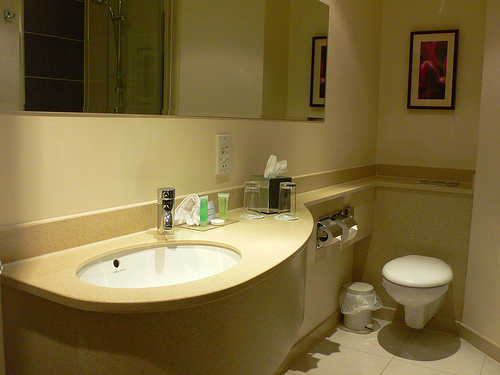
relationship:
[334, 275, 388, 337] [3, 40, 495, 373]
trash can in a bathroom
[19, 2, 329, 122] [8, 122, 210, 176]
mirror on wall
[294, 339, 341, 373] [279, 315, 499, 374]
shadows on floor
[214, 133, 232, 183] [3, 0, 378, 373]
outlet on wall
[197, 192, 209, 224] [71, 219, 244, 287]
shampoo on sink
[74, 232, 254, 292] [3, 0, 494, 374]
sink in bathroom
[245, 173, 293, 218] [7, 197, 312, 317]
box on counter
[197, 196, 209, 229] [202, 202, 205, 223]
bottle of soap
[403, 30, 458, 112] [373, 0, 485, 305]
picture on wall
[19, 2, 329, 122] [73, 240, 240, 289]
mirror above sink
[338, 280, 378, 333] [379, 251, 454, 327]
trash can next to toilet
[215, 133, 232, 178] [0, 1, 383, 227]
outlet on wall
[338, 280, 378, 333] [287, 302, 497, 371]
trash can on floor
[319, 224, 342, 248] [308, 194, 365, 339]
paper roll on wall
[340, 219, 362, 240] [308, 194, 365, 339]
paper roll on wall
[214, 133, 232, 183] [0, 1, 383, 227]
outlet on wall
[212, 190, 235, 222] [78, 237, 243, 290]
hand wash on sink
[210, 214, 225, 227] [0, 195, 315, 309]
soap on counter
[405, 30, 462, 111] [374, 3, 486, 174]
frame on wall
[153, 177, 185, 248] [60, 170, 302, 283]
faucet on sink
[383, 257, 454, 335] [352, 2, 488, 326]
toilet on wall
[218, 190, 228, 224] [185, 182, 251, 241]
bottle of soap